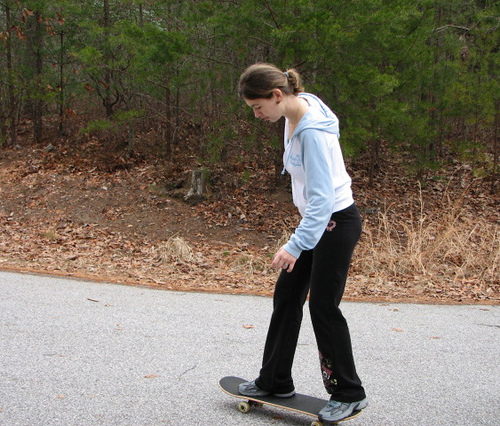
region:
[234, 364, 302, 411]
Right gray shoe on skater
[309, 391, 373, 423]
Left gray shoe on skater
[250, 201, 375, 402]
Black pants of skater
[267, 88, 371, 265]
White sweater on skater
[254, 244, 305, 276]
Left hand of skater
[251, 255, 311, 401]
Right leg of skater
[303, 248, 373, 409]
Left leg of skater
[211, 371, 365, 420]
Skateboard skater is on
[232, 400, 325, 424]
Wheels on skater's skateboard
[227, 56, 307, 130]
Head of skater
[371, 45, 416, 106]
the leaves of a tree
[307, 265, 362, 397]
the leg of a person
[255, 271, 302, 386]
the leg of a person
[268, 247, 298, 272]
the hand of a person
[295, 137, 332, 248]
the arm of a person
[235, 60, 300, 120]
the head of a person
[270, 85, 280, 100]
the ear of a person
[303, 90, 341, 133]
a blue hoodie of a jacket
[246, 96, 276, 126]
the face of a person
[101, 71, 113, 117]
the trunk of a tree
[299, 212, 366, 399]
woman wearing black pants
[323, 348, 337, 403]
woman has pattern on pants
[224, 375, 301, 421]
woman riding on black skateboard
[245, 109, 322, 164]
woman is looking down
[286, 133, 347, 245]
woman wearing blue shirt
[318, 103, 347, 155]
blue shirt has hood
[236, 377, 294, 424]
woman wearing gray pants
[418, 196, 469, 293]
dry grass behind woman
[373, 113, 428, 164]
green bushes behind grass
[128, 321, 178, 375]
woman skateboarding on street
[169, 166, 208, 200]
dried decrepit stimp with mold on it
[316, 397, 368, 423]
left shoe with gray and dark gray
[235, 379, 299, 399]
girl's right shoe that is light gray and dark gray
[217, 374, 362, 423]
skateboard with black paper on top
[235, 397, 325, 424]
small off white wheels for a skateboard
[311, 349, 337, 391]
small little floral design on the girl's pants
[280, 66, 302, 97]
hair in a nice little ponytail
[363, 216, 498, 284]
dry dead grass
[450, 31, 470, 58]
either a wasp nest or some unknown animal's nest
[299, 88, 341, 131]
white hood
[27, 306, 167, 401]
a smooth grey side walk.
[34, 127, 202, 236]
dirt inside of a forest.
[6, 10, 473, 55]
a bunch of green trees.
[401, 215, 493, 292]
the grass is brown .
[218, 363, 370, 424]
a grey skate board.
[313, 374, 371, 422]
a women is wearing blue sneakers.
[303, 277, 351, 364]
a woman is wearing black pants.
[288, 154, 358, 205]
a woman is wearing a light blue jacket.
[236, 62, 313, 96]
a woman is wearing a short pony tail.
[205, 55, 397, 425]
a woman is skate boarding in the street.